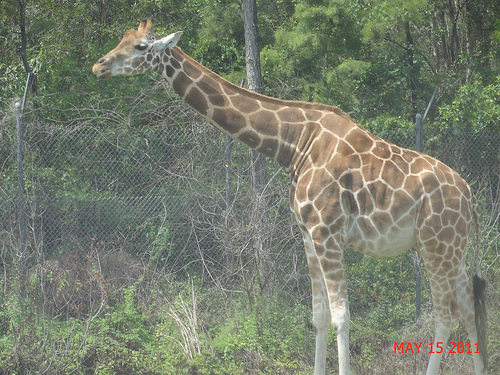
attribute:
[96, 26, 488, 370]
giraffe — standing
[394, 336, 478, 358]
date — printed in red